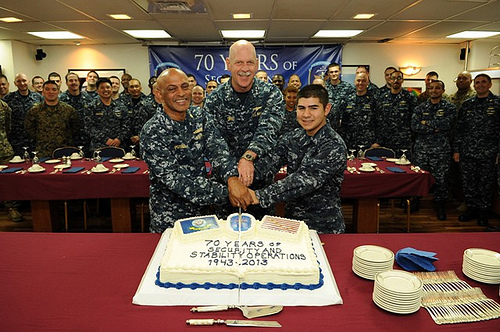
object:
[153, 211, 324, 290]
cake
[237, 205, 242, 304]
knife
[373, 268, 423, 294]
dishes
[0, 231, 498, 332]
table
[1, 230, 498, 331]
tablecloth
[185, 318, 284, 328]
knives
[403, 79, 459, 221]
men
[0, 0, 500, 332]
photo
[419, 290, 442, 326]
forks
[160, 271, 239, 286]
icing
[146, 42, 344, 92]
banner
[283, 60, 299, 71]
words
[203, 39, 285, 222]
man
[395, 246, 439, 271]
napkin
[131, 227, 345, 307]
napkin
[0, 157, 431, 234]
table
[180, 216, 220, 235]
images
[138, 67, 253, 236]
man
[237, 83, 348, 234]
man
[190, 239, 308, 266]
lettering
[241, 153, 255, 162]
watch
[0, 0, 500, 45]
lights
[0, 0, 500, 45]
ceiling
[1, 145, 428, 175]
settings